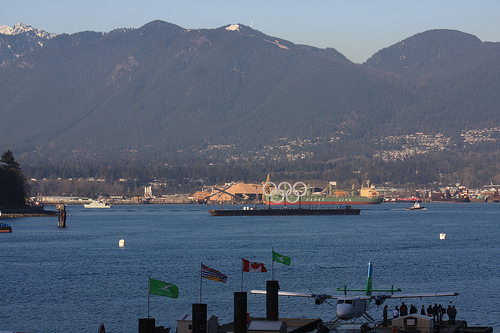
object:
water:
[0, 202, 500, 318]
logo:
[261, 181, 308, 204]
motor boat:
[83, 198, 113, 210]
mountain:
[1, 18, 367, 164]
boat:
[389, 198, 430, 211]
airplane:
[249, 261, 461, 323]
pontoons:
[152, 315, 491, 333]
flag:
[273, 250, 292, 266]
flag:
[199, 262, 229, 284]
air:
[13, 4, 493, 323]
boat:
[204, 193, 361, 218]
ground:
[221, 130, 500, 184]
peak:
[5, 15, 53, 47]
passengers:
[451, 305, 456, 323]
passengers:
[382, 302, 389, 326]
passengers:
[392, 305, 399, 320]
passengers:
[399, 299, 409, 317]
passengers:
[410, 302, 419, 315]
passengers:
[420, 304, 426, 315]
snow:
[226, 25, 240, 29]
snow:
[6, 25, 38, 32]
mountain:
[354, 25, 500, 153]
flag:
[242, 257, 270, 273]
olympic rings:
[259, 181, 308, 205]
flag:
[148, 278, 178, 298]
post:
[137, 317, 157, 333]